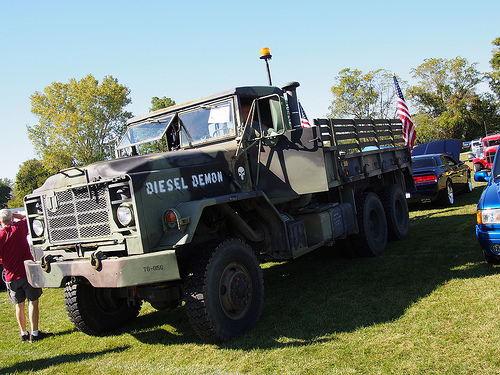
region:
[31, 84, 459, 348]
truck in army colors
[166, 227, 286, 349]
black wheels on truck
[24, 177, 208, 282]
front lights of truck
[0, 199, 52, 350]
man in red shirt by truck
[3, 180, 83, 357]
man wearing hat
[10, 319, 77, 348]
white socks of man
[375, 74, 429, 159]
flag of the united states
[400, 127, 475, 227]
black car with hood open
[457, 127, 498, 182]
red vehicle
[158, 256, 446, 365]
green grass under truck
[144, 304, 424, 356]
shadow cast on the ground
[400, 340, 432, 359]
small white spots on the grass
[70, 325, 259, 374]
freshly cut green grass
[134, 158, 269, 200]
white words on green truck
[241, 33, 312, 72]
yellow light on top of the trunk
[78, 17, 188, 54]
clear blue skies overhead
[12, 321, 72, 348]
man wearing blue sneakers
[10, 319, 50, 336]
short white socks on man's foot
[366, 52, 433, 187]
large American flag on back of truck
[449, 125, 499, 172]
red truck in the back ground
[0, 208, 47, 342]
a man in a red t-shirt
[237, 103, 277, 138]
a man is sitting in the diesel demon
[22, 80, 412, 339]
a military diesel truck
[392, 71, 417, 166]
the American flag displayed on the truck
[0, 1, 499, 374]
a daytime outdoor picture of an auto show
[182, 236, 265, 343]
the diesel trucks front wheel and tire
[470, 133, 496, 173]
a red hot rod behind the diesel demon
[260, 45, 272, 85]
a security bubble light above the truck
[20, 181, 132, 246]
the front grill and headlights of the truck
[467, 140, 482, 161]
a white hot rod in the distance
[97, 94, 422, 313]
green and white military vehicle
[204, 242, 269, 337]
gray vehicle tire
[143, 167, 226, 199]
white writing on vehicle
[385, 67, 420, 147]
red, white and blue flag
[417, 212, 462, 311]
shadow of military vehicle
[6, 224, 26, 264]
man wearing red shirt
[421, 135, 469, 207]
black car with upraised hood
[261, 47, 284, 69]
yellow light on vehicle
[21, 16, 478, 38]
white clouds against blue sky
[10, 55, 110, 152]
tree with green leaves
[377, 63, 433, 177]
American flag attached to car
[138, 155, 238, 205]
Diesel Demon white text on truck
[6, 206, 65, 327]
man with red shirt and gray pants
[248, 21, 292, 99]
orange and black pole on car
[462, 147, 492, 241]
electric blue sedan car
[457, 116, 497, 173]
red pickup track in distance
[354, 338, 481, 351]
light green grass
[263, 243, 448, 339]
shadow from large black truck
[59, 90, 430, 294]
camo armored pick up truck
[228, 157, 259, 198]
white skull painted on truck